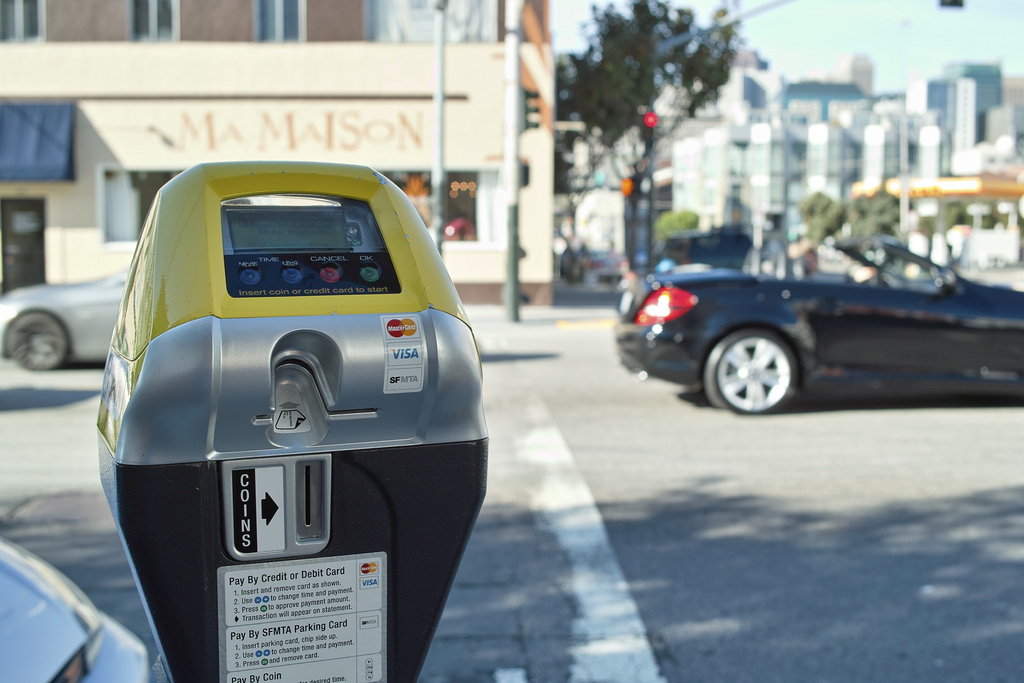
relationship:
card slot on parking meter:
[253, 330, 393, 423] [96, 155, 512, 678]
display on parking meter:
[218, 196, 383, 288] [96, 155, 512, 678]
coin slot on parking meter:
[215, 453, 333, 553] [96, 155, 512, 678]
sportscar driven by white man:
[616, 229, 1022, 422] [784, 225, 826, 276]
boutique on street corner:
[0, 26, 566, 302] [456, 278, 649, 329]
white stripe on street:
[499, 376, 664, 680] [0, 329, 1015, 680]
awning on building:
[0, 99, 86, 189] [0, 0, 555, 307]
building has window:
[0, 0, 555, 307] [106, 3, 206, 27]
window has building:
[280, 0, 304, 45] [0, 0, 555, 307]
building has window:
[0, 38, 561, 310] [392, 168, 503, 244]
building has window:
[0, 0, 555, 307] [254, 2, 306, 42]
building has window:
[0, 0, 555, 307] [131, 2, 177, 42]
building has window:
[0, 0, 555, 307] [1, 2, 40, 38]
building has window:
[0, 0, 555, 307] [386, 169, 482, 242]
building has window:
[0, 0, 555, 307] [102, 169, 172, 240]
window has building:
[0, 4, 42, 46] [0, 0, 555, 307]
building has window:
[0, 0, 555, 307] [253, 0, 302, 45]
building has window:
[0, 0, 555, 307] [261, 0, 300, 40]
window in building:
[398, 169, 498, 247] [136, 26, 605, 312]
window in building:
[0, 0, 43, 46] [0, 0, 555, 307]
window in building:
[129, 0, 181, 41] [0, 0, 555, 307]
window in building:
[256, 0, 308, 42] [0, 0, 555, 307]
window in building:
[93, 158, 486, 242] [0, 0, 555, 307]